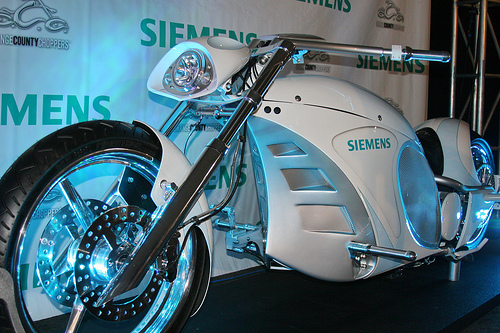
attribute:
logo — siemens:
[0, 92, 111, 127]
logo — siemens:
[138, 17, 258, 49]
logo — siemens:
[354, 52, 426, 74]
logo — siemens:
[299, 0, 351, 12]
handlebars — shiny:
[294, 39, 491, 100]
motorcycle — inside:
[26, 40, 490, 290]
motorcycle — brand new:
[3, 27, 495, 285]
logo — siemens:
[0, 84, 120, 134]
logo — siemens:
[343, 136, 395, 153]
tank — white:
[291, 68, 450, 271]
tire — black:
[1, 119, 205, 329]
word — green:
[346, 137, 392, 151]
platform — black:
[4, 237, 484, 329]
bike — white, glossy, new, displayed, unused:
[4, 32, 494, 329]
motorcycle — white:
[73, 56, 455, 281]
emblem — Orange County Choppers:
[0, 0, 73, 58]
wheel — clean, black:
[0, 110, 212, 330]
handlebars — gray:
[247, 31, 453, 66]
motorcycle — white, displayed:
[2, 37, 497, 328]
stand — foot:
[442, 245, 474, 292]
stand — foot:
[423, 238, 481, 299]